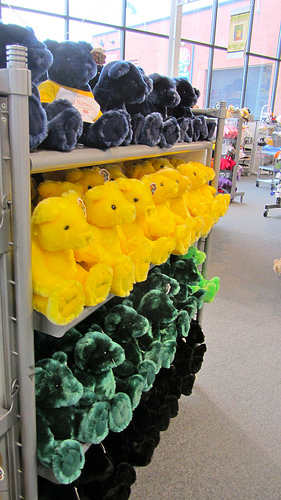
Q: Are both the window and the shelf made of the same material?
A: No, the window is made of glass and the shelf is made of metal.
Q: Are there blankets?
A: No, there are no blankets.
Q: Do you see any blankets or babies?
A: No, there are no blankets or babies.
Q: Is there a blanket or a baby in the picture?
A: No, there are no blankets or babies.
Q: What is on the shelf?
A: The stuffed animal is on the shelf.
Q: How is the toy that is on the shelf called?
A: The toy is a stuffed animal.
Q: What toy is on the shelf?
A: The toy is a stuffed animal.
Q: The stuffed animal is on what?
A: The stuffed animal is on the shelf.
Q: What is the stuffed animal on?
A: The stuffed animal is on the shelf.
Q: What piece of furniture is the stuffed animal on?
A: The stuffed animal is on the shelf.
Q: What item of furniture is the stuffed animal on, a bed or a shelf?
A: The stuffed animal is on a shelf.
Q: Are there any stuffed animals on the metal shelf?
A: Yes, there is a stuffed animal on the shelf.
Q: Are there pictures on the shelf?
A: No, there is a stuffed animal on the shelf.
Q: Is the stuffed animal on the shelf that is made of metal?
A: Yes, the stuffed animal is on the shelf.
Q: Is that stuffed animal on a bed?
A: No, the stuffed animal is on the shelf.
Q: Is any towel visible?
A: No, there are no towels.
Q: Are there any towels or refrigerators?
A: No, there are no towels or refrigerators.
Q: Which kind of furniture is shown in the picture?
A: The furniture is a shelf.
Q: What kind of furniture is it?
A: The piece of furniture is a shelf.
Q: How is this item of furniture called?
A: This is a shelf.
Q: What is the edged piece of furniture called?
A: The piece of furniture is a shelf.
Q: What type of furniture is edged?
A: The furniture is a shelf.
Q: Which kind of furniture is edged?
A: The furniture is a shelf.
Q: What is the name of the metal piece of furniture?
A: The piece of furniture is a shelf.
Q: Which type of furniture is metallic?
A: The furniture is a shelf.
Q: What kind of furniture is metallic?
A: The furniture is a shelf.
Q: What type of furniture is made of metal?
A: The furniture is a shelf.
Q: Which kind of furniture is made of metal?
A: The furniture is a shelf.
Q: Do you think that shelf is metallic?
A: Yes, the shelf is metallic.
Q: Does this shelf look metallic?
A: Yes, the shelf is metallic.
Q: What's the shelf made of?
A: The shelf is made of metal.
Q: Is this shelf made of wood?
A: No, the shelf is made of metal.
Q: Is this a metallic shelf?
A: Yes, this is a metallic shelf.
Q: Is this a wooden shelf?
A: No, this is a metallic shelf.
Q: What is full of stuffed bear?
A: The shelf is full of stuffed bear.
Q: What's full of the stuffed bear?
A: The shelf is full of stuffed bear.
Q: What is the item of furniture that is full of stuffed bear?
A: The piece of furniture is a shelf.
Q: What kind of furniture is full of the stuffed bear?
A: The piece of furniture is a shelf.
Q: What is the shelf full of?
A: The shelf is full of stuffed bear.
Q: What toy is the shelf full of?
A: The shelf is full of stuffed bear.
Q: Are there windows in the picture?
A: Yes, there is a window.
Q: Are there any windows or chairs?
A: Yes, there is a window.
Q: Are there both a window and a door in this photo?
A: No, there is a window but no doors.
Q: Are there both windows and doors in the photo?
A: No, there is a window but no doors.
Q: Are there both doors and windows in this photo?
A: No, there is a window but no doors.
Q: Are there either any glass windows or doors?
A: Yes, there is a glass window.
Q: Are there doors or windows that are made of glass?
A: Yes, the window is made of glass.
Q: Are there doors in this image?
A: No, there are no doors.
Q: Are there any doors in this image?
A: No, there are no doors.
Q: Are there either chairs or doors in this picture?
A: No, there are no doors or chairs.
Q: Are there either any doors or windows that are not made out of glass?
A: No, there is a window but it is made of glass.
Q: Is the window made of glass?
A: Yes, the window is made of glass.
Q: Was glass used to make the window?
A: Yes, the window is made of glass.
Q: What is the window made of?
A: The window is made of glass.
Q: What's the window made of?
A: The window is made of glass.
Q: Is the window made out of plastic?
A: No, the window is made of glass.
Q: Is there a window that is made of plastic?
A: No, there is a window but it is made of glass.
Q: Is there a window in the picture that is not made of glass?
A: No, there is a window but it is made of glass.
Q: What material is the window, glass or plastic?
A: The window is made of glass.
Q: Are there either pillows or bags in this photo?
A: No, there are no pillows or bags.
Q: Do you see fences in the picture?
A: No, there are no fences.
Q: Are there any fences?
A: No, there are no fences.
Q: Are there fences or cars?
A: No, there are no fences or cars.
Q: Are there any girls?
A: No, there are no girls.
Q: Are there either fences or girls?
A: No, there are no girls or fences.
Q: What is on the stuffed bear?
A: The shirt is on the stuffed bear.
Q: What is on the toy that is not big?
A: The shirt is on the stuffed bear.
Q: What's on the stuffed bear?
A: The shirt is on the stuffed bear.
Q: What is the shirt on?
A: The shirt is on the stuffed bear.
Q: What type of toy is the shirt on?
A: The shirt is on the stuffed bear.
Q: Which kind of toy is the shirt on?
A: The shirt is on the stuffed bear.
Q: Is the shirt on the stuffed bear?
A: Yes, the shirt is on the stuffed bear.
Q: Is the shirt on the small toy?
A: Yes, the shirt is on the stuffed bear.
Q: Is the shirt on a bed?
A: No, the shirt is on the stuffed bear.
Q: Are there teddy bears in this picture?
A: Yes, there is a teddy bear.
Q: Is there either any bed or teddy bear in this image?
A: Yes, there is a teddy bear.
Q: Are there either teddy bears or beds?
A: Yes, there is a teddy bear.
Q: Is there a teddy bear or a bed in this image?
A: Yes, there is a teddy bear.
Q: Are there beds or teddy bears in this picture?
A: Yes, there is a teddy bear.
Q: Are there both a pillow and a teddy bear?
A: No, there is a teddy bear but no pillows.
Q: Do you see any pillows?
A: No, there are no pillows.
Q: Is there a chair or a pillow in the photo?
A: No, there are no pillows or chairs.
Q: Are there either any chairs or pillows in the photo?
A: No, there are no pillows or chairs.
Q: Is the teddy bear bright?
A: Yes, the teddy bear is bright.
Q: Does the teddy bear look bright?
A: Yes, the teddy bear is bright.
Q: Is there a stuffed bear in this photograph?
A: Yes, there is a stuffed bear.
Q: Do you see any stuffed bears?
A: Yes, there is a stuffed bear.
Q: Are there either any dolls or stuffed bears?
A: Yes, there is a stuffed bear.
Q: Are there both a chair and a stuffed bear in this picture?
A: No, there is a stuffed bear but no chairs.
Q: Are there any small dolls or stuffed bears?
A: Yes, there is a small stuffed bear.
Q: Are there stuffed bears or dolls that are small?
A: Yes, the stuffed bear is small.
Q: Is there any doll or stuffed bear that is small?
A: Yes, the stuffed bear is small.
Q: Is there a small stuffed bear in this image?
A: Yes, there is a small stuffed bear.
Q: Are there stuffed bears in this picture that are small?
A: Yes, there is a stuffed bear that is small.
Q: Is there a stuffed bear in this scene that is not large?
A: Yes, there is a small stuffed bear.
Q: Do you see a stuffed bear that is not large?
A: Yes, there is a small stuffed bear.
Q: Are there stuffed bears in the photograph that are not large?
A: Yes, there is a small stuffed bear.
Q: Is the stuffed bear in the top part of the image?
A: Yes, the stuffed bear is in the top of the image.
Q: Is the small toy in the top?
A: Yes, the stuffed bear is in the top of the image.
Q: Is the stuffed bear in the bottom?
A: No, the stuffed bear is in the top of the image.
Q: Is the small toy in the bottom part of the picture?
A: No, the stuffed bear is in the top of the image.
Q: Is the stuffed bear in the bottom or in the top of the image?
A: The stuffed bear is in the top of the image.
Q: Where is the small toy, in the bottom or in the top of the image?
A: The stuffed bear is in the top of the image.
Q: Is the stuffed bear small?
A: Yes, the stuffed bear is small.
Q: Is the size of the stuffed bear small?
A: Yes, the stuffed bear is small.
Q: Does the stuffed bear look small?
A: Yes, the stuffed bear is small.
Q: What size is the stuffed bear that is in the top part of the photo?
A: The stuffed bear is small.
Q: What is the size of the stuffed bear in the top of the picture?
A: The stuffed bear is small.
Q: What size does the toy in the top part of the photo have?
A: The stuffed bear has small size.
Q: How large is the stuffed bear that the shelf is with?
A: The stuffed bear is small.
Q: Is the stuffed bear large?
A: No, the stuffed bear is small.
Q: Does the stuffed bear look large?
A: No, the stuffed bear is small.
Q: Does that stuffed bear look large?
A: No, the stuffed bear is small.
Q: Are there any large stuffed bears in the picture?
A: No, there is a stuffed bear but it is small.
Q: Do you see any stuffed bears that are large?
A: No, there is a stuffed bear but it is small.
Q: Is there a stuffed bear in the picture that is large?
A: No, there is a stuffed bear but it is small.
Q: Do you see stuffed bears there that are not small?
A: No, there is a stuffed bear but it is small.